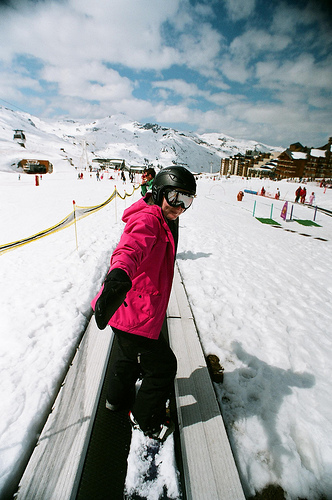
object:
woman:
[90, 165, 197, 444]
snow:
[1, 107, 332, 497]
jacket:
[90, 193, 175, 340]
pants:
[109, 329, 178, 431]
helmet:
[152, 166, 196, 204]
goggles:
[164, 188, 196, 211]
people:
[294, 186, 323, 206]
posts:
[252, 200, 318, 227]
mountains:
[0, 105, 264, 173]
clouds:
[32, 4, 112, 63]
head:
[152, 166, 199, 221]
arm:
[107, 215, 160, 287]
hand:
[94, 271, 135, 331]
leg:
[130, 339, 178, 415]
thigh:
[127, 332, 177, 375]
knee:
[164, 343, 177, 382]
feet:
[126, 407, 165, 448]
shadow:
[162, 342, 316, 481]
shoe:
[129, 414, 178, 445]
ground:
[243, 227, 329, 496]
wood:
[12, 297, 247, 499]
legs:
[106, 330, 140, 400]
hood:
[121, 194, 159, 223]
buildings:
[263, 140, 330, 178]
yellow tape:
[1, 186, 136, 256]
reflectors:
[69, 196, 81, 249]